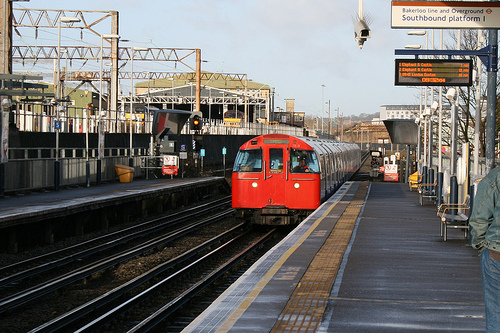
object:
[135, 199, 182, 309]
line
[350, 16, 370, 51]
camera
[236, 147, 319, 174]
windshield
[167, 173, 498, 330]
ground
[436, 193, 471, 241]
bench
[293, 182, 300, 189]
headlight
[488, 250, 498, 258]
brown tag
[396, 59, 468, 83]
sign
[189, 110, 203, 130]
light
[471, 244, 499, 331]
jeans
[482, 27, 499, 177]
pole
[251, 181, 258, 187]
light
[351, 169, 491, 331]
sidewalk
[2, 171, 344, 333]
railway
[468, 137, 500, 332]
man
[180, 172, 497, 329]
platform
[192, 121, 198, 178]
pole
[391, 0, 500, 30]
sign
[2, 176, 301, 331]
railway line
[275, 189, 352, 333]
yellow brick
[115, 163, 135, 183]
bucket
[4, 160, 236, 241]
platform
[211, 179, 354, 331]
line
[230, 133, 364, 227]
red train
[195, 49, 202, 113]
pole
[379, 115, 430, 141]
panel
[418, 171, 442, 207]
seating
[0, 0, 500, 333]
station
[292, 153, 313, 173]
person